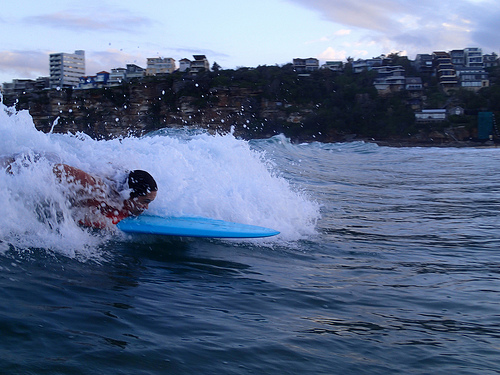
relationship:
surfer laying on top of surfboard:
[1, 156, 161, 217] [130, 212, 284, 247]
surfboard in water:
[130, 212, 284, 247] [258, 128, 489, 374]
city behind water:
[17, 56, 479, 142] [258, 128, 489, 374]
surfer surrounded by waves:
[1, 156, 161, 217] [107, 131, 305, 235]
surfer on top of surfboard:
[1, 156, 161, 217] [130, 212, 284, 247]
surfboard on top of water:
[130, 212, 284, 247] [258, 128, 489, 374]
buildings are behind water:
[0, 50, 478, 88] [258, 128, 489, 374]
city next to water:
[17, 56, 479, 142] [258, 128, 489, 374]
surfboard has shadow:
[130, 212, 284, 247] [119, 240, 247, 280]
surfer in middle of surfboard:
[1, 156, 161, 217] [130, 212, 284, 247]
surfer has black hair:
[1, 156, 161, 217] [124, 166, 156, 202]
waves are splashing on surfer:
[107, 131, 305, 235] [1, 156, 161, 217]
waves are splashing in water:
[107, 131, 305, 235] [258, 128, 489, 374]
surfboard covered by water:
[130, 212, 284, 247] [258, 128, 489, 374]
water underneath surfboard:
[258, 128, 489, 374] [130, 212, 284, 247]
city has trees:
[17, 56, 479, 142] [205, 68, 411, 133]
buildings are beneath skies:
[0, 50, 478, 88] [3, 3, 484, 57]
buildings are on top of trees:
[0, 50, 478, 88] [205, 68, 411, 133]